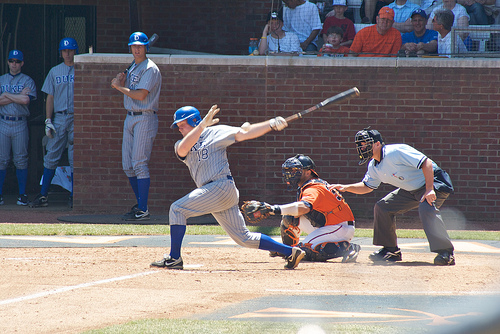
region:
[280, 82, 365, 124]
A WOODEN BASEBALL BAT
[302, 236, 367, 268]
CATCHERS SHIN GUARDS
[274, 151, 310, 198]
A BLACK CATCHERS MASK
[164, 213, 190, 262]
A BLUE SOCK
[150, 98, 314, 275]
A BASEBALL PLAYER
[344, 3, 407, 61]
MAN WEARING AN ORANGE SHIRT AND HAT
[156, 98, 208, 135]
BLUE BASEBALL HAT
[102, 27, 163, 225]
A BASEBALL PLAYER HOLDING A BAT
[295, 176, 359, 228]
A ORANGE SHIRT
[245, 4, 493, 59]
PEOPLE WATCHING THE GAME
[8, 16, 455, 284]
A baseball game.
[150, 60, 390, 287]
The man has a bat in his left hand.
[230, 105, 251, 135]
A baseball.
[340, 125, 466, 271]
The umpire is standing behind the catcher.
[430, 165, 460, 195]
The umpire has a blue bag.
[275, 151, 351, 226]
The catcher is wearing an orange shirt.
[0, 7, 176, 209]
Baseball players watching the game.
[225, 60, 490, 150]
A brick wall.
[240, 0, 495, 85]
A crowd is watching the game.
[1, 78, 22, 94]
The player's school's name is written on the uniform.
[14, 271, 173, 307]
Brown dirt on a baseball field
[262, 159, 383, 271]
Catcher in an orange shirt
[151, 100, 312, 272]
Baseball player swinging a bat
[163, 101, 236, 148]
Blue helmet on a baseball player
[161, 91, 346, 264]
Baseball player wearing blue and gray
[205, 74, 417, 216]
Brick wall by a baseball field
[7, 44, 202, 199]
Baseball players watching the game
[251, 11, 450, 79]
Fans watching the baseball game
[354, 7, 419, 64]
Man in a orange hat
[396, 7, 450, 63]
Man in a blue shirt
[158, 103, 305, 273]
batter swinging the bat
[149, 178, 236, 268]
left leg of batter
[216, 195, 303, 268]
right leg of batter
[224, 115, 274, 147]
left arm of batter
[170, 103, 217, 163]
right arm of batter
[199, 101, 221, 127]
right hand of batter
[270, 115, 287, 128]
left hand of batter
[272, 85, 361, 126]
bat the player is using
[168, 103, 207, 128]
blue helmet of batter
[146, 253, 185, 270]
left foot of batter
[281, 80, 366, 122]
A Baseball bat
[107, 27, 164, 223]
A baseball player standing in the background with a bat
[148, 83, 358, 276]
A baseball player squatting with his arms and bat in the air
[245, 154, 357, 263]
A player with headgear kneeling on the ground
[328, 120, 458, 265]
Player bending with headgear and his hand on the other players back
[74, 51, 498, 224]
A red brick wall with a silver stone top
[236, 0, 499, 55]
Fans watching the game behind a mesh fence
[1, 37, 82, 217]
Two other players standing in the background off the baseball field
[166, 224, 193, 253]
A baseball players blue sock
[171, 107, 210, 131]
The baseball players blue hat